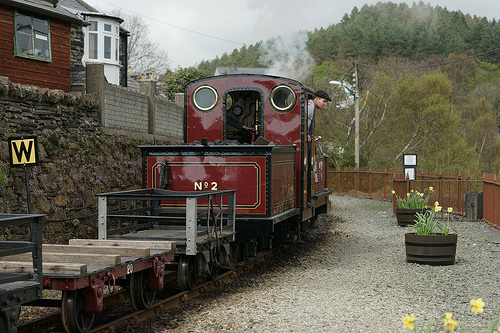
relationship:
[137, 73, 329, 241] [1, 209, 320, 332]
train on track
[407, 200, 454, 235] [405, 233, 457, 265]
daffodil in planter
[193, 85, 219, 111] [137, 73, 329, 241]
window on train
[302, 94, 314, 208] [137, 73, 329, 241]
door of train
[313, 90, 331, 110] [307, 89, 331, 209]
head of man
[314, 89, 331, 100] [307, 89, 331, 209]
hat of man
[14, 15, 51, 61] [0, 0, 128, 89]
window on building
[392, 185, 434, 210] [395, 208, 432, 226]
flower in planter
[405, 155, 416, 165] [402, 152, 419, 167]
sign in frame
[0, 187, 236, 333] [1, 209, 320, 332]
cars on track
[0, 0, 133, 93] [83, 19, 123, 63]
building with windows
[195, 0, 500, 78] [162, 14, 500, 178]
trees on hill